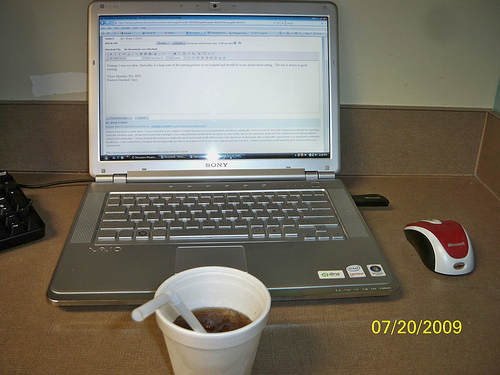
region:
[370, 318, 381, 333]
yellow colored print number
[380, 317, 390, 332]
yellow colored print number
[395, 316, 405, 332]
yellow colored print number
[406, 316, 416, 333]
yellow colored print number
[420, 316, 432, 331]
yellow colored print number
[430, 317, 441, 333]
yellow colored print number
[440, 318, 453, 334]
yellow colored print number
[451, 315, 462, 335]
yellow colored print number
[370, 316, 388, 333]
yellow colored prints numbers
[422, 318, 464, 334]
yellow colored print numbers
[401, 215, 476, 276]
wireless mouse by computer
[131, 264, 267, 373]
white styrofoam cup on table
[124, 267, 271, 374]
cup has bent straw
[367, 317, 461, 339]
yellow date stamp near right corner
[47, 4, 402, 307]
grey computer on desk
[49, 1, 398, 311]
the computer is laptop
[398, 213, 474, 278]
mouse sitting by laptop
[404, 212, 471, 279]
mouse is red, white, and black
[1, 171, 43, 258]
black keyboard on desk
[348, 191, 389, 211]
usb drive stuck in laptop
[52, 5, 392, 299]
a silver colored laptop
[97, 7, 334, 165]
a computer screen turned on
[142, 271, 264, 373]
a white Styrofoam cup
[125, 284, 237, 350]
a white straw in a drink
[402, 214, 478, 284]
a red, black, and white computer mouse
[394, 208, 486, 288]
a wireless computer mouse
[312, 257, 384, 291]
stickers on a laptop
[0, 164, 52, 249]
a black computer keyboard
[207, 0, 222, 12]
a built in laptop webcam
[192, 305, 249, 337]
ice in a drink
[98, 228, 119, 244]
silver button on laptop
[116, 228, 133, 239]
silver button on laptop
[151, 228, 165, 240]
silver button on laptop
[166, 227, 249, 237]
silver button on laptop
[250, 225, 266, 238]
silver button on laptop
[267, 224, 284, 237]
silver button on laptop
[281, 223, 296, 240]
silver button on laptop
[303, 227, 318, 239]
silver button on laptop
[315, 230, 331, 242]
silver button on laptop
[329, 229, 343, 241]
silver button on laptop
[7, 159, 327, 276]
two laptops are on the table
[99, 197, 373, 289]
the laptop is gray incolor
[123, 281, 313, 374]
a plastic cup on the table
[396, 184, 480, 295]
the mouse is next to the laptop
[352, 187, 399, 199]
the flash is coneccted to thw laptop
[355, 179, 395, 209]
the flash disk is black in color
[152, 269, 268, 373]
the tin contains some driinks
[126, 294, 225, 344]
the straw is in the tin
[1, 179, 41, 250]
the laptop is black in color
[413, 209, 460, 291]
the mouse is black red and white i color